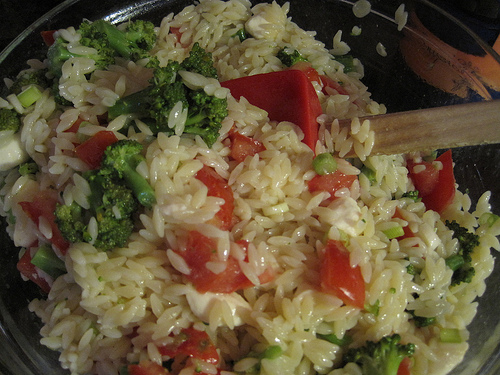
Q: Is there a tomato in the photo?
A: Yes, there is a tomato.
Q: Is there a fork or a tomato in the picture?
A: Yes, there is a tomato.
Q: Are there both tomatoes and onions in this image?
A: No, there is a tomato but no onions.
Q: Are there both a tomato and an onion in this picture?
A: No, there is a tomato but no onions.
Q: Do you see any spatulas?
A: Yes, there is a spatula.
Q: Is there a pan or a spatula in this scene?
A: Yes, there is a spatula.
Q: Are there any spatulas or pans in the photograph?
A: Yes, there is a spatula.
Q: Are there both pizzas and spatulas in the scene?
A: No, there is a spatula but no pizzas.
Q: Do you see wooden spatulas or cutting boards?
A: Yes, there is a wood spatula.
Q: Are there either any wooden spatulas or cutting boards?
A: Yes, there is a wood spatula.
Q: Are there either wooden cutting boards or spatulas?
A: Yes, there is a wood spatula.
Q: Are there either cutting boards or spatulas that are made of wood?
A: Yes, the spatula is made of wood.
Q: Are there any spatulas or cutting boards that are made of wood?
A: Yes, the spatula is made of wood.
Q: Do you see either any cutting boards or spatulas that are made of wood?
A: Yes, the spatula is made of wood.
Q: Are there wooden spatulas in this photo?
A: Yes, there is a wood spatula.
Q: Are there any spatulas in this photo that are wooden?
A: Yes, there is a spatula that is wooden.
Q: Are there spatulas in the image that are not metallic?
A: Yes, there is a wooden spatula.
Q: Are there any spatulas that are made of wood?
A: Yes, there is a spatula that is made of wood.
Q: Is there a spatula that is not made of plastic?
A: Yes, there is a spatula that is made of wood.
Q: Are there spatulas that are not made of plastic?
A: Yes, there is a spatula that is made of wood.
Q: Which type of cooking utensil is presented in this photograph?
A: The cooking utensil is a spatula.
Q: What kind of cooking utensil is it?
A: The cooking utensil is a spatula.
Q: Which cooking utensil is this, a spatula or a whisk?
A: That is a spatula.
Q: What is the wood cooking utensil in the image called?
A: The cooking utensil is a spatula.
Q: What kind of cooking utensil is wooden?
A: The cooking utensil is a spatula.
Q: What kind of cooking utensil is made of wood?
A: The cooking utensil is a spatula.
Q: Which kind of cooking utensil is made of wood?
A: The cooking utensil is a spatula.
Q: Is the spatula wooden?
A: Yes, the spatula is wooden.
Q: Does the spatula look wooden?
A: Yes, the spatula is wooden.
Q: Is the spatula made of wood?
A: Yes, the spatula is made of wood.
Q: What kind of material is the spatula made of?
A: The spatula is made of wood.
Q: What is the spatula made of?
A: The spatula is made of wood.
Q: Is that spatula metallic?
A: No, the spatula is wooden.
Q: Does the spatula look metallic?
A: No, the spatula is wooden.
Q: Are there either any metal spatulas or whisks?
A: No, there is a spatula but it is wooden.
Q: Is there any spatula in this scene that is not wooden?
A: No, there is a spatula but it is wooden.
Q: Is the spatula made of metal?
A: No, the spatula is made of wood.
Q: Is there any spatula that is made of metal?
A: No, there is a spatula but it is made of wood.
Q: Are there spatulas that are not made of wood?
A: No, there is a spatula but it is made of wood.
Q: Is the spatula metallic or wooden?
A: The spatula is wooden.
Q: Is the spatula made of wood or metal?
A: The spatula is made of wood.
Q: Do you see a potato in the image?
A: No, there are no potatoes.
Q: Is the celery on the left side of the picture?
A: Yes, the celery is on the left of the image.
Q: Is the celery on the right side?
A: No, the celery is on the left of the image.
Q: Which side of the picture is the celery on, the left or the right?
A: The celery is on the left of the image.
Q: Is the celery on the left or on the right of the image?
A: The celery is on the left of the image.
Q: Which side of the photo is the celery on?
A: The celery is on the left of the image.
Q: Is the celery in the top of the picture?
A: Yes, the celery is in the top of the image.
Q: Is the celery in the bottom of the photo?
A: No, the celery is in the top of the image.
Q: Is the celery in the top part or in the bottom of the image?
A: The celery is in the top of the image.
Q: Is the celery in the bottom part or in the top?
A: The celery is in the top of the image.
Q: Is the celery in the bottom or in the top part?
A: The celery is in the top of the image.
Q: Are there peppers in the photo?
A: Yes, there is a pepper.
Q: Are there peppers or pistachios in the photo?
A: Yes, there is a pepper.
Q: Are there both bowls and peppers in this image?
A: Yes, there are both a pepper and a bowl.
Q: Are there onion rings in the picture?
A: No, there are no onion rings.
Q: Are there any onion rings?
A: No, there are no onion rings.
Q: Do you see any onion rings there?
A: No, there are no onion rings.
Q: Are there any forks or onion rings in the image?
A: No, there are no onion rings or forks.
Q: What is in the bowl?
A: The pepper is in the bowl.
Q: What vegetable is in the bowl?
A: The vegetable is a pepper.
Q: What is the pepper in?
A: The pepper is in the bowl.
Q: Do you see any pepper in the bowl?
A: Yes, there is a pepper in the bowl.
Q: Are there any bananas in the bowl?
A: No, there is a pepper in the bowl.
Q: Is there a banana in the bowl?
A: No, there is a pepper in the bowl.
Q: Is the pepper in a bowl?
A: Yes, the pepper is in a bowl.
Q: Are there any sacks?
A: No, there are no sacks.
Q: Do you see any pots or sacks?
A: No, there are no sacks or pots.